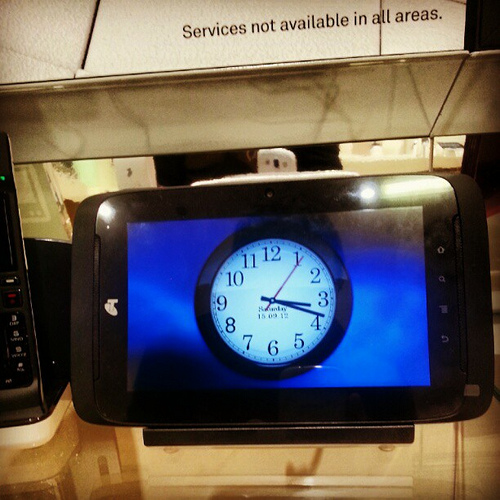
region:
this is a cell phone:
[80, 174, 472, 424]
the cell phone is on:
[124, 197, 421, 393]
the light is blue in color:
[363, 257, 415, 379]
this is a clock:
[204, 225, 344, 363]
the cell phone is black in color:
[460, 180, 476, 230]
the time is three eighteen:
[207, 244, 331, 348]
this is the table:
[323, 450, 398, 498]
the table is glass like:
[338, 447, 405, 498]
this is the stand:
[220, 71, 330, 135]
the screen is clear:
[115, 210, 425, 366]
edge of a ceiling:
[248, 50, 293, 95]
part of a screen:
[366, 319, 405, 366]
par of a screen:
[341, 339, 386, 407]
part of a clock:
[268, 332, 329, 424]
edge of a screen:
[342, 383, 389, 441]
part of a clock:
[273, 334, 311, 395]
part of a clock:
[259, 339, 294, 383]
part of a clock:
[276, 309, 316, 367]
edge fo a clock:
[274, 352, 307, 393]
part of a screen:
[391, 340, 427, 385]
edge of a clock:
[301, 333, 336, 400]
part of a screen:
[341, 375, 376, 434]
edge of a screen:
[235, 389, 289, 457]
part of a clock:
[261, 348, 300, 426]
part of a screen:
[359, 335, 394, 391]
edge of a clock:
[253, 341, 313, 415]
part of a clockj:
[284, 318, 307, 348]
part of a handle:
[356, 418, 398, 468]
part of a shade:
[263, 57, 303, 119]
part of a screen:
[366, 340, 393, 382]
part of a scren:
[267, 343, 309, 439]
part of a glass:
[312, 340, 344, 400]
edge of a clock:
[233, 338, 284, 400]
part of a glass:
[377, 346, 412, 393]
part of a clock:
[286, 315, 350, 407]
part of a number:
[266, 319, 285, 346]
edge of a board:
[234, 351, 280, 412]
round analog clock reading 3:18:
[192, 215, 352, 381]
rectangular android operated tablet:
[67, 168, 496, 429]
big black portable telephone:
[0, 125, 50, 430]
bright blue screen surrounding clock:
[124, 203, 432, 392]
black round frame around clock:
[192, 219, 354, 381]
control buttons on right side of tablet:
[435, 243, 450, 344]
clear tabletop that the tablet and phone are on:
[0, 351, 499, 498]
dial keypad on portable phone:
[0, 274, 30, 375]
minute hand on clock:
[259, 295, 326, 319]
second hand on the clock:
[262, 252, 305, 314]